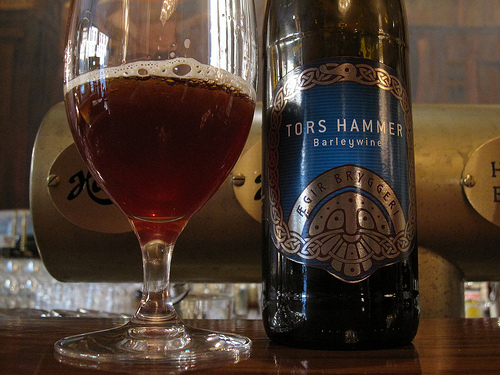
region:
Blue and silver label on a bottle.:
[267, 54, 409, 289]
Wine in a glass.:
[66, 61, 257, 251]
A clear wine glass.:
[60, 3, 259, 368]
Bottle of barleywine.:
[264, 0, 421, 354]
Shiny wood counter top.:
[0, 316, 492, 367]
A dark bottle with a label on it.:
[260, 1, 424, 350]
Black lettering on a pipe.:
[64, 157, 117, 215]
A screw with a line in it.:
[43, 172, 60, 187]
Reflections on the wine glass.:
[64, 0, 250, 72]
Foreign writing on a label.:
[291, 162, 403, 224]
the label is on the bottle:
[263, 0, 420, 345]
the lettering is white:
[281, 117, 405, 149]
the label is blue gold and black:
[263, 56, 420, 281]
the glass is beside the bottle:
[51, 3, 420, 369]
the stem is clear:
[137, 248, 178, 324]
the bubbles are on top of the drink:
[61, 55, 258, 223]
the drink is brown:
[58, 59, 258, 229]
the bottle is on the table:
[257, 3, 499, 373]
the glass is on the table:
[53, 0, 255, 365]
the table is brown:
[0, 320, 499, 368]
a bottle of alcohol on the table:
[283, 133, 470, 369]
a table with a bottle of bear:
[262, 166, 439, 367]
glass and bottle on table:
[32, 76, 408, 368]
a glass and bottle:
[44, 53, 401, 365]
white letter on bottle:
[283, 116, 293, 141]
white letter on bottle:
[292, 120, 304, 137]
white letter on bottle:
[302, 118, 314, 134]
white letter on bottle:
[315, 113, 328, 133]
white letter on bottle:
[332, 110, 346, 134]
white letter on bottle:
[346, 112, 360, 136]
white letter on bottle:
[356, 112, 376, 135]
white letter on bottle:
[373, 114, 388, 138]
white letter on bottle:
[385, 117, 395, 137]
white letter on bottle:
[394, 119, 403, 139]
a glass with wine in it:
[39, 5, 268, 372]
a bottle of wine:
[247, 3, 428, 353]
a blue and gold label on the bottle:
[264, 57, 423, 289]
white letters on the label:
[278, 113, 408, 157]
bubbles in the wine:
[128, 57, 193, 84]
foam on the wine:
[57, 52, 261, 109]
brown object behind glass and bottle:
[21, 89, 498, 364]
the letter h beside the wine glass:
[59, 159, 115, 216]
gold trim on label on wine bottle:
[257, 57, 422, 288]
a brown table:
[1, 309, 498, 372]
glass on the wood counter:
[0, 270, 13, 310]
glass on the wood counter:
[16, 266, 28, 314]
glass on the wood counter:
[31, 270, 47, 308]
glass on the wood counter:
[61, 282, 81, 314]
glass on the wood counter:
[103, 282, 124, 317]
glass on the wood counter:
[202, 293, 234, 328]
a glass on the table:
[60, 2, 253, 357]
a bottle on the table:
[258, 7, 420, 352]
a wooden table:
[8, 313, 485, 373]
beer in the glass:
[63, 65, 258, 235]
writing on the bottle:
[286, 118, 409, 149]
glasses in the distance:
[3, 260, 268, 331]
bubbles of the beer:
[151, 58, 239, 90]